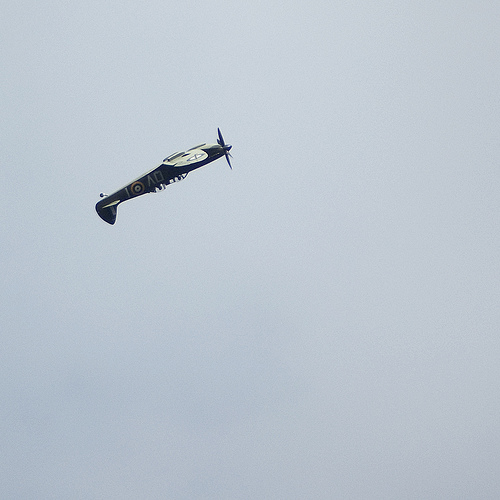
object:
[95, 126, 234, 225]
jet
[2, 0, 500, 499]
sky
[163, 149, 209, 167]
wing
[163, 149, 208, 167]
bottom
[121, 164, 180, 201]
side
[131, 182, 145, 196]
target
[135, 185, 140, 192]
circle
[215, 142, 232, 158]
front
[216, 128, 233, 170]
propeller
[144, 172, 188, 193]
cockpit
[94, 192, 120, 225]
back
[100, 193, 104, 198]
wheel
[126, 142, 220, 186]
underbelly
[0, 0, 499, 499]
clouds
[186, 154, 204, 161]
logo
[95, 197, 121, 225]
tail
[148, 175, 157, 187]
letter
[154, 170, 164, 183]
letter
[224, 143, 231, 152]
engine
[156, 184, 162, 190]
person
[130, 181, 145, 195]
circle